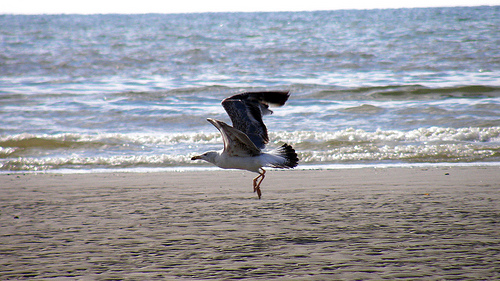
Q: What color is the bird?
A: White and black.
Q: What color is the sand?
A: A little tan.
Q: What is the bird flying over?
A: The sand.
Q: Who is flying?
A: The bird.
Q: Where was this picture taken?
A: On the beach.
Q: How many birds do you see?
A: Only one.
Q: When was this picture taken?
A: In the day.